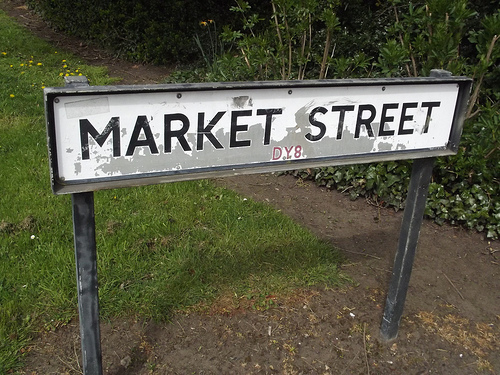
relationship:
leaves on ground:
[428, 182, 499, 229] [228, 164, 498, 300]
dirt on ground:
[418, 261, 447, 296] [3, 3, 498, 368]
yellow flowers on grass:
[3, 49, 85, 101] [3, 16, 343, 362]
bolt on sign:
[166, 91, 184, 105] [27, 64, 486, 199]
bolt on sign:
[276, 83, 298, 98] [27, 64, 486, 199]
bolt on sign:
[370, 86, 390, 93] [27, 64, 486, 199]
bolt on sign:
[46, 95, 65, 108] [27, 64, 486, 199]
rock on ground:
[117, 353, 134, 373] [3, 3, 498, 368]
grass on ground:
[119, 195, 311, 308] [105, 190, 345, 307]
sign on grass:
[11, 48, 490, 208] [126, 187, 308, 309]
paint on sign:
[56, 88, 458, 176] [11, 48, 490, 208]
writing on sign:
[71, 103, 471, 166] [0, 75, 475, 367]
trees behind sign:
[195, 12, 499, 77] [43, 68, 464, 180]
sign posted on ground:
[41, 76, 476, 195] [3, 3, 498, 368]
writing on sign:
[304, 99, 441, 143] [38, 72, 478, 194]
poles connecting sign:
[70, 159, 431, 373] [43, 68, 464, 180]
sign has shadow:
[41, 76, 476, 195] [124, 213, 381, 373]